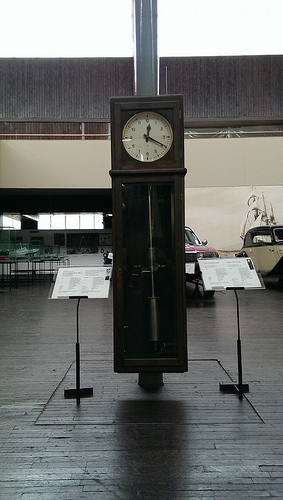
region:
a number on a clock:
[142, 116, 151, 124]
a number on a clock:
[153, 118, 160, 126]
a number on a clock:
[157, 124, 166, 132]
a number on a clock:
[159, 140, 167, 150]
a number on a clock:
[151, 146, 159, 154]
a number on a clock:
[143, 148, 153, 158]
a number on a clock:
[135, 145, 142, 155]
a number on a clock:
[127, 141, 136, 151]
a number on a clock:
[126, 132, 134, 142]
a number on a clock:
[129, 122, 135, 131]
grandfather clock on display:
[101, 88, 209, 389]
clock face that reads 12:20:
[114, 106, 181, 165]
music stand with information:
[44, 257, 121, 414]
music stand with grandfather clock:
[197, 250, 268, 410]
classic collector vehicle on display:
[185, 221, 281, 267]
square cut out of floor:
[35, 328, 258, 473]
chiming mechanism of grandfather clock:
[120, 172, 186, 372]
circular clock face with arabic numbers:
[114, 106, 183, 169]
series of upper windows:
[4, 207, 105, 235]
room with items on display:
[35, 107, 274, 459]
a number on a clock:
[144, 116, 149, 122]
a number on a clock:
[155, 118, 159, 125]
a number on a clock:
[159, 123, 164, 131]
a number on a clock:
[161, 133, 167, 138]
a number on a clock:
[154, 148, 160, 156]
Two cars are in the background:
[183, 216, 279, 299]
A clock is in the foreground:
[100, 78, 195, 379]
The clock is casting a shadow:
[103, 392, 199, 495]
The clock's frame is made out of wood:
[99, 87, 195, 381]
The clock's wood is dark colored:
[102, 89, 194, 381]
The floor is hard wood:
[13, 424, 265, 488]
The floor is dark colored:
[13, 423, 266, 490]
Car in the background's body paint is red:
[185, 223, 226, 302]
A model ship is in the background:
[7, 236, 41, 262]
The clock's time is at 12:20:
[105, 96, 187, 168]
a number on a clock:
[160, 131, 169, 141]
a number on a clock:
[159, 140, 165, 146]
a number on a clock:
[145, 149, 152, 156]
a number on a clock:
[128, 134, 133, 140]